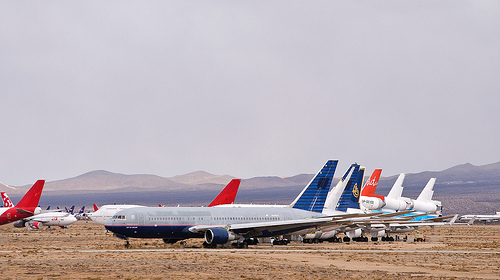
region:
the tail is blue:
[305, 161, 342, 218]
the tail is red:
[368, 165, 383, 195]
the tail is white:
[390, 172, 408, 202]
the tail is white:
[417, 179, 438, 200]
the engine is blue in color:
[204, 222, 232, 248]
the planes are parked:
[110, 158, 452, 261]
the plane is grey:
[116, 188, 299, 254]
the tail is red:
[5, 180, 42, 215]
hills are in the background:
[109, 149, 496, 183]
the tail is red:
[216, 168, 257, 211]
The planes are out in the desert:
[1, 72, 491, 277]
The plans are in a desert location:
[0, 76, 486, 276]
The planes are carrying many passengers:
[1, 70, 496, 270]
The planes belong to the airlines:
[12, 106, 478, 277]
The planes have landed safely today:
[1, 92, 497, 263]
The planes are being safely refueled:
[6, 82, 496, 272]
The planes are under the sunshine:
[0, 81, 495, 266]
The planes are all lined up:
[1, 76, 487, 258]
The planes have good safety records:
[0, 102, 493, 268]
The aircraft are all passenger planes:
[1, 90, 488, 278]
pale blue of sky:
[3, 3, 497, 176]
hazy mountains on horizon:
[0, 160, 499, 203]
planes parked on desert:
[0, 159, 450, 247]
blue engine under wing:
[203, 227, 238, 244]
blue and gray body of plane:
[105, 161, 336, 242]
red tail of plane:
[214, 177, 242, 205]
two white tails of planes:
[387, 174, 441, 200]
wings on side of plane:
[195, 208, 453, 243]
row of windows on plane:
[147, 214, 284, 221]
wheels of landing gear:
[327, 231, 401, 244]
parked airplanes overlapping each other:
[90, 160, 455, 245]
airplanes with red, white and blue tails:
[285, 155, 440, 226]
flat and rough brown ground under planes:
[7, 217, 492, 272]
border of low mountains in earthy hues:
[1, 161, 491, 203]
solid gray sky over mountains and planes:
[2, 2, 493, 184]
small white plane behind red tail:
[12, 177, 72, 229]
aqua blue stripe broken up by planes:
[360, 200, 430, 220]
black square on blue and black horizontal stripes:
[291, 155, 336, 210]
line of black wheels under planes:
[225, 226, 392, 242]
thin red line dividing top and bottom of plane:
[85, 175, 196, 243]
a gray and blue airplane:
[104, 161, 341, 247]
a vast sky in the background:
[1, 3, 498, 143]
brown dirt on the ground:
[4, 252, 135, 277]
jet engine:
[202, 226, 239, 246]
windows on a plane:
[108, 213, 130, 223]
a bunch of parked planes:
[83, 163, 487, 254]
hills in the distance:
[73, 166, 215, 197]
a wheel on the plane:
[121, 238, 133, 248]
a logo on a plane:
[348, 181, 364, 202]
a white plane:
[459, 208, 497, 223]